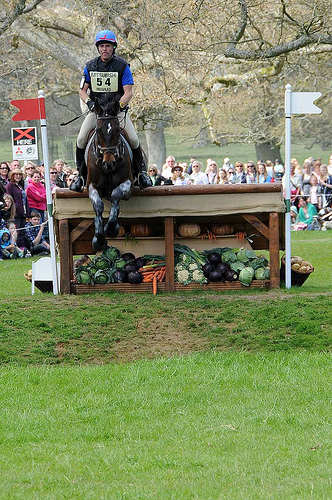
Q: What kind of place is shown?
A: It is a field.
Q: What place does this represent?
A: It represents the field.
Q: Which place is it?
A: It is a field.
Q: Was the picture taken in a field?
A: Yes, it was taken in a field.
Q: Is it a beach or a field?
A: It is a field.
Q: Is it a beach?
A: No, it is a field.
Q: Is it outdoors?
A: Yes, it is outdoors.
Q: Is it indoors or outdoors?
A: It is outdoors.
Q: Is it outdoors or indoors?
A: It is outdoors.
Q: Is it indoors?
A: No, it is outdoors.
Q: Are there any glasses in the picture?
A: No, there are no glasses.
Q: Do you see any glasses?
A: No, there are no glasses.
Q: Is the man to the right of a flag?
A: Yes, the man is to the right of a flag.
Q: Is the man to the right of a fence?
A: No, the man is to the right of a flag.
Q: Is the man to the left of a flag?
A: No, the man is to the right of a flag.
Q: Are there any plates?
A: No, there are no plates.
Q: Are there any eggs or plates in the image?
A: No, there are no plates or eggs.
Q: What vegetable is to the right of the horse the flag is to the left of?
A: The vegetable is a pumpkin.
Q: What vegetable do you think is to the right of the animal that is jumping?
A: The vegetable is a pumpkin.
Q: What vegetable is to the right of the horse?
A: The vegetable is a pumpkin.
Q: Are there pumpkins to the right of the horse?
A: Yes, there is a pumpkin to the right of the horse.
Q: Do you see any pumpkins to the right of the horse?
A: Yes, there is a pumpkin to the right of the horse.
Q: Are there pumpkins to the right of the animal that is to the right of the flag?
A: Yes, there is a pumpkin to the right of the horse.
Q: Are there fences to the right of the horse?
A: No, there is a pumpkin to the right of the horse.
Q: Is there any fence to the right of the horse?
A: No, there is a pumpkin to the right of the horse.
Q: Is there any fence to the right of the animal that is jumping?
A: No, there is a pumpkin to the right of the horse.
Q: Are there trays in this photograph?
A: No, there are no trays.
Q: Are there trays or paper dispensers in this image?
A: No, there are no trays or paper dispensers.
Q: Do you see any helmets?
A: Yes, there is a helmet.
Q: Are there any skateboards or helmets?
A: Yes, there is a helmet.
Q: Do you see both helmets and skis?
A: No, there is a helmet but no skis.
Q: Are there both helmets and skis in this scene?
A: No, there is a helmet but no skis.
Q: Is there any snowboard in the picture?
A: No, there are no snowboards.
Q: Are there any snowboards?
A: No, there are no snowboards.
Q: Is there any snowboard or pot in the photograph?
A: No, there are no snowboards or pots.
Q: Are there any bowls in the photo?
A: No, there are no bowls.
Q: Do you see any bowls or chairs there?
A: No, there are no bowls or chairs.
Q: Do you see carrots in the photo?
A: Yes, there are carrots.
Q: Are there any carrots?
A: Yes, there are carrots.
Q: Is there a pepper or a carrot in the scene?
A: Yes, there are carrots.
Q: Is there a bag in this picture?
A: No, there are no bags.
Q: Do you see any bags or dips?
A: No, there are no bags or dips.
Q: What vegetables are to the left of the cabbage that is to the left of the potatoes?
A: The vegetables are carrots.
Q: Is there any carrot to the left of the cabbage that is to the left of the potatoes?
A: Yes, there are carrots to the left of the cabbage.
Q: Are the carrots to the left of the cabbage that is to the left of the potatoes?
A: Yes, the carrots are to the left of the cabbage.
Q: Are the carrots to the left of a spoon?
A: No, the carrots are to the left of the cabbage.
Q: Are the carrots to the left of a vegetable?
A: No, the carrots are to the right of a vegetable.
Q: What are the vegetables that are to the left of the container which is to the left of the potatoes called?
A: The vegetables are carrots.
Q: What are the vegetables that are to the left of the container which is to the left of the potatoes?
A: The vegetables are carrots.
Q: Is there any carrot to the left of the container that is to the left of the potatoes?
A: Yes, there are carrots to the left of the container.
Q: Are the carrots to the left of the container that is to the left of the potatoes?
A: Yes, the carrots are to the left of the container.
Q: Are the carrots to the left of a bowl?
A: No, the carrots are to the left of the container.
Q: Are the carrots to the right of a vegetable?
A: Yes, the carrots are to the right of a vegetable.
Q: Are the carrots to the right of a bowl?
A: No, the carrots are to the right of a vegetable.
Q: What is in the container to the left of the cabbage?
A: The carrots are in the container.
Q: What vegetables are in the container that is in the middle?
A: The vegetables are carrots.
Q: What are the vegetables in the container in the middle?
A: The vegetables are carrots.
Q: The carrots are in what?
A: The carrots are in the container.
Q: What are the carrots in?
A: The carrots are in the container.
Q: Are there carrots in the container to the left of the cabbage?
A: Yes, there are carrots in the container.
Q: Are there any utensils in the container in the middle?
A: No, there are carrots in the container.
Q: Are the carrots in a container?
A: Yes, the carrots are in a container.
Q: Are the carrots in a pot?
A: No, the carrots are in a container.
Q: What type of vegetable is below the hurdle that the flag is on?
A: The vegetables are carrots.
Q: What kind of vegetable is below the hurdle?
A: The vegetables are carrots.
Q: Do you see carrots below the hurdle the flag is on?
A: Yes, there are carrots below the hurdle.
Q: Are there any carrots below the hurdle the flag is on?
A: Yes, there are carrots below the hurdle.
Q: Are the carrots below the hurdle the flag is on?
A: Yes, the carrots are below the hurdle.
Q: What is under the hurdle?
A: The carrots are under the hurdle.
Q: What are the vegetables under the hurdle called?
A: The vegetables are carrots.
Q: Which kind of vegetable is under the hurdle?
A: The vegetables are carrots.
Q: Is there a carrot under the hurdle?
A: Yes, there are carrots under the hurdle.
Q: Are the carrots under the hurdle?
A: Yes, the carrots are under the hurdle.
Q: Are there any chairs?
A: No, there are no chairs.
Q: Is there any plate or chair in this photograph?
A: No, there are no chairs or plates.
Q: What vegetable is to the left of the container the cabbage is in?
A: The vegetable is a pumpkin.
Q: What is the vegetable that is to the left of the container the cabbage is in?
A: The vegetable is a pumpkin.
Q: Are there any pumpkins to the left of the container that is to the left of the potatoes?
A: Yes, there is a pumpkin to the left of the container.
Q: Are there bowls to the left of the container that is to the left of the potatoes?
A: No, there is a pumpkin to the left of the container.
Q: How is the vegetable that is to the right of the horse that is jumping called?
A: The vegetable is a pumpkin.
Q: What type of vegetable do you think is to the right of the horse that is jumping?
A: The vegetable is a pumpkin.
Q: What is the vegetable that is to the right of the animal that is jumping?
A: The vegetable is a pumpkin.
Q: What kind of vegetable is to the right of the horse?
A: The vegetable is a pumpkin.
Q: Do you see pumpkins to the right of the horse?
A: Yes, there is a pumpkin to the right of the horse.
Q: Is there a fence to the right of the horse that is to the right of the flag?
A: No, there is a pumpkin to the right of the horse.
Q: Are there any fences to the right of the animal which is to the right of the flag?
A: No, there is a pumpkin to the right of the horse.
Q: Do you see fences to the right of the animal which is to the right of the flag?
A: No, there is a pumpkin to the right of the horse.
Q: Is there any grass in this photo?
A: Yes, there is grass.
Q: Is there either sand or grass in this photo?
A: Yes, there is grass.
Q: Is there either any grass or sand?
A: Yes, there is grass.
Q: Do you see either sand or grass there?
A: Yes, there is grass.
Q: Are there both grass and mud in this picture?
A: No, there is grass but no mud.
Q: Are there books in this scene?
A: No, there are no books.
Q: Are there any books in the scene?
A: No, there are no books.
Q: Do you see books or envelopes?
A: No, there are no books or envelopes.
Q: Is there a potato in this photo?
A: Yes, there are potatoes.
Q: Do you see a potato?
A: Yes, there are potatoes.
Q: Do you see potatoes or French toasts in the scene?
A: Yes, there are potatoes.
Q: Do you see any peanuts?
A: No, there are no peanuts.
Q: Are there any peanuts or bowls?
A: No, there are no peanuts or bowls.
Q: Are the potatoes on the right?
A: Yes, the potatoes are on the right of the image.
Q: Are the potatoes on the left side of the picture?
A: No, the potatoes are on the right of the image.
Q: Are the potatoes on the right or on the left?
A: The potatoes are on the right of the image.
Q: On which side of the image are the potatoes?
A: The potatoes are on the right of the image.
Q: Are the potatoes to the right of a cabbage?
A: Yes, the potatoes are to the right of a cabbage.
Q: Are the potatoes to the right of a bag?
A: No, the potatoes are to the right of a cabbage.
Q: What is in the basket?
A: The potatoes are in the basket.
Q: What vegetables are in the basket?
A: The vegetables are potatoes.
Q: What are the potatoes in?
A: The potatoes are in the basket.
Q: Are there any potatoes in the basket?
A: Yes, there are potatoes in the basket.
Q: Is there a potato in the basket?
A: Yes, there are potatoes in the basket.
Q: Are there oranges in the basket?
A: No, there are potatoes in the basket.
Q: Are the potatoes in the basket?
A: Yes, the potatoes are in the basket.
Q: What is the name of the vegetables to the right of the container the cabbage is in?
A: The vegetables are potatoes.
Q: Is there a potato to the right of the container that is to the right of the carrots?
A: Yes, there are potatoes to the right of the container.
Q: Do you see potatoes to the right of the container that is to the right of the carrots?
A: Yes, there are potatoes to the right of the container.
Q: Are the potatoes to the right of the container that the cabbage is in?
A: Yes, the potatoes are to the right of the container.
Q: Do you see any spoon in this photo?
A: No, there are no spoons.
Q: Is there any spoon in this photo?
A: No, there are no spoons.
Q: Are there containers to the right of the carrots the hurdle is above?
A: Yes, there is a container to the right of the carrots.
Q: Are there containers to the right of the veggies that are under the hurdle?
A: Yes, there is a container to the right of the carrots.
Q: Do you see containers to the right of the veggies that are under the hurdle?
A: Yes, there is a container to the right of the carrots.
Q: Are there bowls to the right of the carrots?
A: No, there is a container to the right of the carrots.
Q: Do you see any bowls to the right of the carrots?
A: No, there is a container to the right of the carrots.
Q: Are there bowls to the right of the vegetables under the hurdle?
A: No, there is a container to the right of the carrots.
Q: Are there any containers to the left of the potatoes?
A: Yes, there is a container to the left of the potatoes.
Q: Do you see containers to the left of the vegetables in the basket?
A: Yes, there is a container to the left of the potatoes.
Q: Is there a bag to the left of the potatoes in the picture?
A: No, there is a container to the left of the potatoes.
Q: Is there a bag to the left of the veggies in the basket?
A: No, there is a container to the left of the potatoes.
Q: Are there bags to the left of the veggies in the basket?
A: No, there is a container to the left of the potatoes.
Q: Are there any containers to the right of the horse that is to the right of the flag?
A: Yes, there is a container to the right of the horse.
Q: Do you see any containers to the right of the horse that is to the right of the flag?
A: Yes, there is a container to the right of the horse.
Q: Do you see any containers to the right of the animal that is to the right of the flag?
A: Yes, there is a container to the right of the horse.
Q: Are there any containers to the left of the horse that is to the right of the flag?
A: No, the container is to the right of the horse.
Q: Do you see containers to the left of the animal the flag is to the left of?
A: No, the container is to the right of the horse.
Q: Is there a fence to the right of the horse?
A: No, there is a container to the right of the horse.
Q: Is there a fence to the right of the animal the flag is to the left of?
A: No, there is a container to the right of the horse.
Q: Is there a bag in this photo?
A: No, there are no bags.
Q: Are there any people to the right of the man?
A: Yes, there are people to the right of the man.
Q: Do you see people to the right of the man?
A: Yes, there are people to the right of the man.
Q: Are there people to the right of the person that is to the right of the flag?
A: Yes, there are people to the right of the man.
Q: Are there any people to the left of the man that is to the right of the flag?
A: No, the people are to the right of the man.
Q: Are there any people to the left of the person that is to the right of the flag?
A: No, the people are to the right of the man.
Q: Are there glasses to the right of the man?
A: No, there are people to the right of the man.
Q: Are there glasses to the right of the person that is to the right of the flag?
A: No, there are people to the right of the man.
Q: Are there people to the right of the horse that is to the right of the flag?
A: Yes, there are people to the right of the horse.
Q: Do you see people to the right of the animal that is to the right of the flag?
A: Yes, there are people to the right of the horse.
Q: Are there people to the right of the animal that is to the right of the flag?
A: Yes, there are people to the right of the horse.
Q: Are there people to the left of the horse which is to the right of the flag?
A: No, the people are to the right of the horse.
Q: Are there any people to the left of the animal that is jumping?
A: No, the people are to the right of the horse.